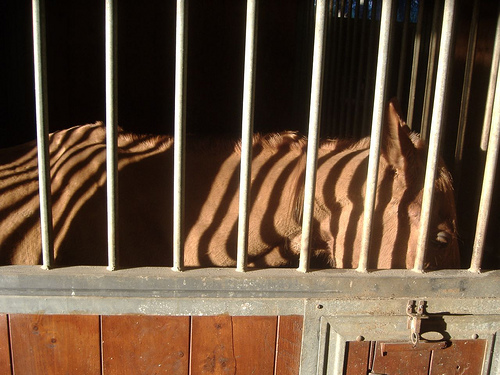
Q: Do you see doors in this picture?
A: Yes, there is a door.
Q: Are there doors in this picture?
A: Yes, there is a door.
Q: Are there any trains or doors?
A: Yes, there is a door.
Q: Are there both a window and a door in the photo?
A: No, there is a door but no windows.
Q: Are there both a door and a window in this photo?
A: No, there is a door but no windows.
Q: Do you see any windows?
A: No, there are no windows.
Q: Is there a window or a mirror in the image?
A: No, there are no windows or mirrors.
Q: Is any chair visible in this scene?
A: No, there are no chairs.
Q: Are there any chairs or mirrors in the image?
A: No, there are no chairs or mirrors.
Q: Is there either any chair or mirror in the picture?
A: No, there are no chairs or mirrors.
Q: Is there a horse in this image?
A: Yes, there is a horse.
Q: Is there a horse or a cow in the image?
A: Yes, there is a horse.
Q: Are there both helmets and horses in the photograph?
A: No, there is a horse but no helmets.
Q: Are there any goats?
A: No, there are no goats.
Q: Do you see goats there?
A: No, there are no goats.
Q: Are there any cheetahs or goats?
A: No, there are no goats or cheetahs.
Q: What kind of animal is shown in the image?
A: The animal is a horse.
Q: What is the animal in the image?
A: The animal is a horse.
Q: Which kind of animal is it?
A: The animal is a horse.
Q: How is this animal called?
A: This is a horse.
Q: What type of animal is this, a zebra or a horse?
A: This is a horse.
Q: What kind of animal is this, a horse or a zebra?
A: This is a horse.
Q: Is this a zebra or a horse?
A: This is a horse.